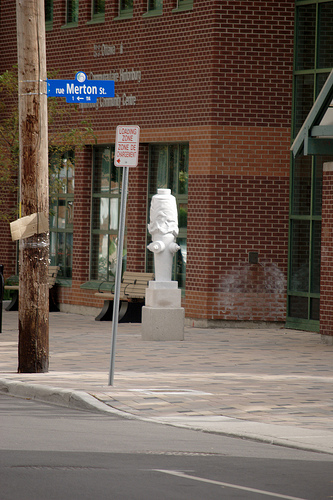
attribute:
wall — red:
[207, 1, 293, 329]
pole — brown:
[13, 6, 52, 367]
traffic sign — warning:
[113, 121, 139, 173]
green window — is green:
[293, 3, 332, 71]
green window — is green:
[290, 72, 331, 141]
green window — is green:
[289, 138, 323, 218]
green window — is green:
[289, 217, 323, 296]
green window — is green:
[287, 291, 319, 328]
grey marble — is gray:
[151, 252, 180, 283]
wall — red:
[4, 0, 285, 315]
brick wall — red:
[0, 0, 288, 323]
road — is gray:
[3, 400, 331, 497]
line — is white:
[160, 466, 308, 498]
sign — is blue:
[46, 66, 116, 108]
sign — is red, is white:
[113, 125, 139, 167]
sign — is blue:
[46, 76, 118, 105]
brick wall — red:
[187, 175, 288, 291]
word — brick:
[119, 89, 140, 108]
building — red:
[1, 1, 290, 321]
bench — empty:
[109, 269, 153, 308]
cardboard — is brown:
[8, 209, 48, 243]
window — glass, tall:
[296, 4, 314, 71]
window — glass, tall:
[291, 74, 313, 137]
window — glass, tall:
[288, 141, 310, 216]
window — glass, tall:
[289, 215, 309, 294]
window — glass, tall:
[287, 293, 309, 320]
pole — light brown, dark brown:
[16, 0, 50, 374]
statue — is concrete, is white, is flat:
[138, 185, 186, 345]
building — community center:
[38, 29, 289, 223]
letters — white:
[66, 83, 99, 96]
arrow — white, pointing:
[74, 93, 87, 103]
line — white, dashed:
[148, 458, 308, 500]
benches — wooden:
[9, 226, 163, 346]